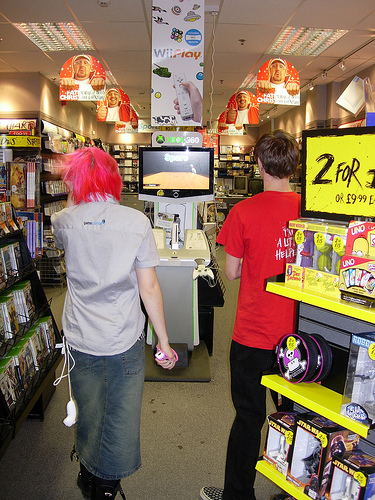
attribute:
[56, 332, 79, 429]
controller — white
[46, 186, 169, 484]
clothing — two different, blue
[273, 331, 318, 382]
purse — black and pink, circle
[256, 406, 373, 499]
star wars — Boxed, figurines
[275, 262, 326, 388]
shelf — black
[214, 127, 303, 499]
man — checkered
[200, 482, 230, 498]
shoes — white and black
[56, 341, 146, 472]
jeans — long, skirt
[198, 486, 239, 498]
shoe — checkered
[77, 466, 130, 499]
shoe — checkered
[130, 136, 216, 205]
tv — black, in a store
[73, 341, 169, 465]
skirt — blue jean, woman's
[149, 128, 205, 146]
sign — xbox 360, display, on tv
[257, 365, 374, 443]
shelf — yellow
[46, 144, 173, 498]
girl — bright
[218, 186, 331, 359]
shirt — red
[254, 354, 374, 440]
shelf — yellow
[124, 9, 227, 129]
banner — wii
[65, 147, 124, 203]
wig — pink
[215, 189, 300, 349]
red shirt — short sleeved 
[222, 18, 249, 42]
ceiling tile — white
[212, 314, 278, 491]
pants — black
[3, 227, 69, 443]
games — video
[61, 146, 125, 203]
hair — red 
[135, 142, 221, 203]
television — black , framed 